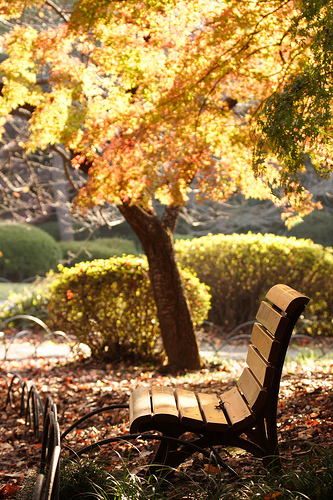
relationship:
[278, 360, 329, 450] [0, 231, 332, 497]
dry leaves on ground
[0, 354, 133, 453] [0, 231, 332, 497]
dry leaves on ground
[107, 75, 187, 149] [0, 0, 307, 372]
leaves on tree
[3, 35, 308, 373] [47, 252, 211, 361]
tree and bush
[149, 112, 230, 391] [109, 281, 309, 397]
leaves next to bench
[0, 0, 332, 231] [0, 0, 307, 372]
leaves on tree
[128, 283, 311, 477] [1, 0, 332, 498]
bench in park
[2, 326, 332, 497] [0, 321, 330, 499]
leaves on ground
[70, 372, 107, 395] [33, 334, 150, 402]
leaves on ground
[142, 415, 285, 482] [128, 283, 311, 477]
base on bench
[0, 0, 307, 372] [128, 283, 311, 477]
tree by bench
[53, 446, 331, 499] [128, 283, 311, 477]
grass by bench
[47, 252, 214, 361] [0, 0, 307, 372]
bush by tree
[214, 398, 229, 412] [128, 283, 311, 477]
object on bench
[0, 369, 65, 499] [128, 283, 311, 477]
fence near bench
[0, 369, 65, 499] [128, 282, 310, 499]
fence near bench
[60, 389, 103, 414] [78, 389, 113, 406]
orange leaves on ground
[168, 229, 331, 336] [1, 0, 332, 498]
bush in park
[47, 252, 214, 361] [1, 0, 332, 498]
bush in park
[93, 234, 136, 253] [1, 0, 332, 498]
bush in park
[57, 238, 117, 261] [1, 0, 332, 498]
bush in park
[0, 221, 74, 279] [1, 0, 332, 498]
bush in park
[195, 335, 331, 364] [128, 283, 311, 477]
walkway near bench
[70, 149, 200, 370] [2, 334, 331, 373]
tree trunk next to pathway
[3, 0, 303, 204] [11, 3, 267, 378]
leaves on tree